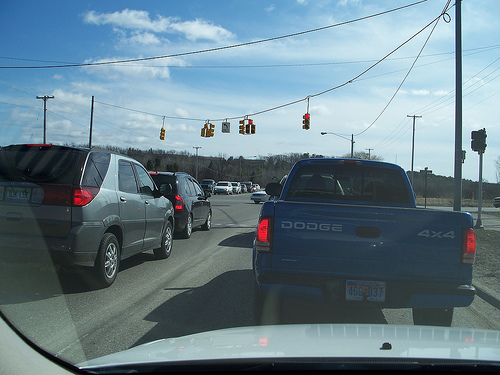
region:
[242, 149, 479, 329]
blue dodge truck sitting at stop light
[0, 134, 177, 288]
grey van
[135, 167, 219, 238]
black van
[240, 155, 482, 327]
blue truck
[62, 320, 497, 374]
hood of white vehicle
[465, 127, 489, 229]
pedestrian walk sign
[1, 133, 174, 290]
grey van sitting behind black van at stop light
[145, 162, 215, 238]
black van sitting in front of grey van at stop light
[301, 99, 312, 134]
stop light with three lights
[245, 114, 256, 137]
stop light with 5 lights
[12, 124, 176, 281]
gray car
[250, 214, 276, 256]
red rear tail light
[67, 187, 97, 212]
red rear light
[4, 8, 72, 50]
white clouds in blue sky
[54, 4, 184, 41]
white clouds in blue sky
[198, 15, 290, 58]
white clouds in blue sky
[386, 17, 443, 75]
white clouds in blue sky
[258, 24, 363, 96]
white clouds in blue sky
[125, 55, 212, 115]
white clouds in blue sky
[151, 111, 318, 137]
street lights hanging up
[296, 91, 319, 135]
street light on red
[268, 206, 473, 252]
a dodge 4x4 in traffic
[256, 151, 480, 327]
a blue truck at stop light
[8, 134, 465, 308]
cars at intersection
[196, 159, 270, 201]
cars stop at red light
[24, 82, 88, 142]
a tall street pole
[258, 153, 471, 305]
blue truck with white lettering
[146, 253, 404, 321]
shadow of blue truck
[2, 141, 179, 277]
cars with tinted windows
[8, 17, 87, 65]
white clouds in blue sky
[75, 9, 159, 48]
white clouds in blue sky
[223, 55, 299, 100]
white clouds in blue sky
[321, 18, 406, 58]
white clouds in blue sky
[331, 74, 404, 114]
white clouds in blue sky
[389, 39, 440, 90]
white clouds in blue sky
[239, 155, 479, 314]
vehicle stopped at traffic light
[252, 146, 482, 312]
blue truck stopped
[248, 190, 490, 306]
vehicle has brake lights on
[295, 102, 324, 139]
traffic light is red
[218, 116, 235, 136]
white traffic sign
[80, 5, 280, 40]
white cloud in blue sky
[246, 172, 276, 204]
car making a left turn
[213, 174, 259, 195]
cars stopped at in intersection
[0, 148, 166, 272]
gray vehicle stopped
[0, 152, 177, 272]
gray car has brake lights on